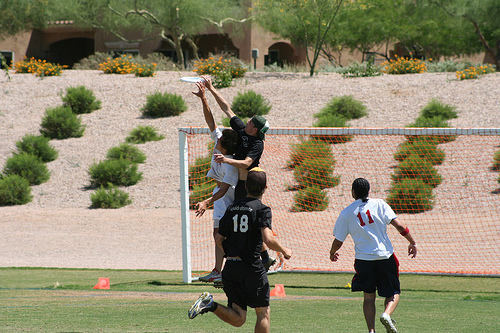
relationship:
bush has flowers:
[102, 55, 154, 75] [116, 57, 130, 69]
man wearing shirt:
[232, 111, 270, 157] [220, 200, 275, 251]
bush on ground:
[140, 94, 188, 116] [123, 90, 134, 100]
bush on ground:
[102, 55, 154, 75] [123, 90, 134, 100]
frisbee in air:
[182, 71, 200, 86] [158, 76, 173, 82]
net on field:
[306, 136, 469, 169] [301, 279, 317, 287]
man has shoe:
[231, 167, 287, 298] [187, 291, 222, 317]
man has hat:
[232, 111, 270, 157] [251, 113, 270, 131]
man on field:
[232, 111, 270, 157] [301, 279, 317, 287]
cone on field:
[87, 278, 120, 292] [301, 279, 317, 287]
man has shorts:
[231, 167, 287, 298] [223, 260, 266, 303]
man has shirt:
[231, 167, 287, 298] [220, 200, 275, 251]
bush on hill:
[140, 94, 188, 116] [35, 80, 183, 242]